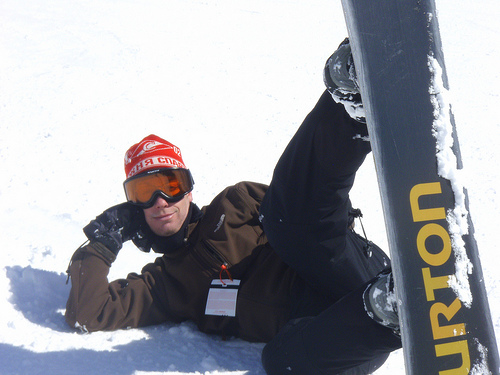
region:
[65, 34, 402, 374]
person laying in the snow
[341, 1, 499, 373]
snowboard attached to feet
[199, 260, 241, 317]
person is wearing tag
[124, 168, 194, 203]
ski goggles on face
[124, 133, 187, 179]
red and white stocking cap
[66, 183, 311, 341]
brown fuzzy jacket is worn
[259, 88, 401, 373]
black ski pants on person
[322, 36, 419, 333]
snow boots attached to snowboard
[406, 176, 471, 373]
yellow letters on snowboard bottom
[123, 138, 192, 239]
the man is smiling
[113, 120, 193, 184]
red beanie with writing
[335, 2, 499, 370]
long black snowboard with snow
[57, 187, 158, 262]
thick black winter gloves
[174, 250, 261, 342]
small white ski lift pass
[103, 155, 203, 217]
bright orange ski goggles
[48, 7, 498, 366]
man posing with snowboard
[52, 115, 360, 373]
man lying in the snow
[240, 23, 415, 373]
thick black ski pants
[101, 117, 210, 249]
man in hat and goggles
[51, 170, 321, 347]
warm brown ski jacket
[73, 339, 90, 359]
the snow is white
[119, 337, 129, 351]
the snow is white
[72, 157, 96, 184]
the snow is white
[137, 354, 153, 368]
the snow is white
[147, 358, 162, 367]
the snow is white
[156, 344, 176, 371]
the snow is white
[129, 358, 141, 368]
the snow is white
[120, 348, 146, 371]
the snow is white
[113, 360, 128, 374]
the snow is white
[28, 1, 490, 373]
this man is a snowboarder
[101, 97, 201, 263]
he is wearing a red boggan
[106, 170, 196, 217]
his goggles have an orange lens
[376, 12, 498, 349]
his board is black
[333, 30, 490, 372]
it has yellow letters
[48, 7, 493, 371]
he's resting his head on his elbow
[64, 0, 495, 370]
he is posing for the photo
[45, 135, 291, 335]
his jacket is brown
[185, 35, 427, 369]
his pants are black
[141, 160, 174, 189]
part of a googles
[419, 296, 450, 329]
part of a letter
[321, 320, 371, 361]
part of a trouser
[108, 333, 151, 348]
edge of a shade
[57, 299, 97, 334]
part of an elbow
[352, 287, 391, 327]
edge of a shoe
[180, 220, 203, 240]
part of a collar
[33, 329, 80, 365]
part of a shade